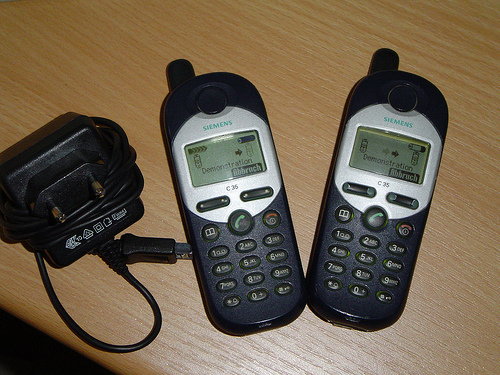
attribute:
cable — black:
[1, 100, 229, 371]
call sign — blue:
[365, 207, 386, 228]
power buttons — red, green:
[232, 210, 254, 234]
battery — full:
[231, 133, 262, 148]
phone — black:
[303, 67, 447, 331]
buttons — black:
[206, 230, 296, 310]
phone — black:
[161, 52, 312, 339]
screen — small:
[349, 125, 430, 192]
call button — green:
[225, 210, 257, 236]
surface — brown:
[251, 20, 351, 130]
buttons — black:
[320, 179, 422, 307]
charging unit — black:
[40, 107, 160, 368]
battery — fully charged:
[237, 133, 257, 143]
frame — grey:
[173, 105, 281, 222]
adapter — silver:
[164, 226, 185, 301]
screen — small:
[180, 132, 278, 189]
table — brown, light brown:
[1, 1, 498, 373]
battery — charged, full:
[16, 114, 171, 343]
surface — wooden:
[247, 17, 336, 119]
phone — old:
[122, 53, 334, 344]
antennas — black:
[163, 46, 398, 93]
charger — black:
[10, 79, 221, 343]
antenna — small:
[156, 57, 203, 82]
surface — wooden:
[0, 0, 498, 372]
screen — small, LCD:
[183, 128, 269, 186]